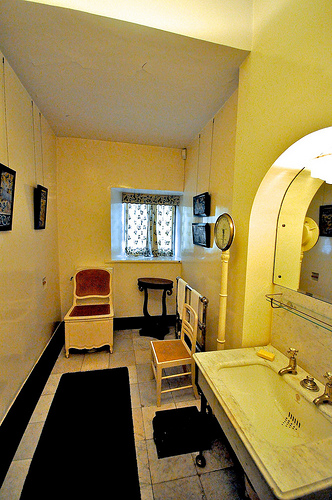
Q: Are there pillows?
A: No, there are no pillows.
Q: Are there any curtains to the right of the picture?
A: Yes, there is a curtain to the right of the picture.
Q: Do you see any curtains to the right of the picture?
A: Yes, there is a curtain to the right of the picture.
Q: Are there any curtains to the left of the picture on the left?
A: No, the curtain is to the right of the picture.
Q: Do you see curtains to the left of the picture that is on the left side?
A: No, the curtain is to the right of the picture.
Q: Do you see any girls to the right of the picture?
A: No, there is a curtain to the right of the picture.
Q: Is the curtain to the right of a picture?
A: Yes, the curtain is to the right of a picture.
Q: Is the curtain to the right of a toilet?
A: No, the curtain is to the right of a picture.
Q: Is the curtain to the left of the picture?
A: No, the curtain is to the right of the picture.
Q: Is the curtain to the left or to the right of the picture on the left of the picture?
A: The curtain is to the right of the picture.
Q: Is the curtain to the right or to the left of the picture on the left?
A: The curtain is to the right of the picture.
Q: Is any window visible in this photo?
A: Yes, there is a window.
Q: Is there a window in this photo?
A: Yes, there is a window.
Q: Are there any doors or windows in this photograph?
A: Yes, there is a window.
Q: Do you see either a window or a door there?
A: Yes, there is a window.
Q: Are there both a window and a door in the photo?
A: No, there is a window but no doors.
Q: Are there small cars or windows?
A: Yes, there is a small window.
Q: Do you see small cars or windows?
A: Yes, there is a small window.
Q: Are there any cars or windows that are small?
A: Yes, the window is small.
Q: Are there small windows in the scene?
A: Yes, there is a small window.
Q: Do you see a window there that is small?
A: Yes, there is a window that is small.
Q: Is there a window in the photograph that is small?
A: Yes, there is a window that is small.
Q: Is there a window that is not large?
A: Yes, there is a small window.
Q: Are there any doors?
A: No, there are no doors.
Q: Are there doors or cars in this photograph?
A: No, there are no doors or cars.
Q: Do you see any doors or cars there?
A: No, there are no doors or cars.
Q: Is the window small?
A: Yes, the window is small.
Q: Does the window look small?
A: Yes, the window is small.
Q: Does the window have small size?
A: Yes, the window is small.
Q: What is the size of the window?
A: The window is small.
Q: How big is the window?
A: The window is small.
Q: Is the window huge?
A: No, the window is small.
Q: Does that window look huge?
A: No, the window is small.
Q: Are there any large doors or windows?
A: No, there is a window but it is small.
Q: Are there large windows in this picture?
A: No, there is a window but it is small.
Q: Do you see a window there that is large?
A: No, there is a window but it is small.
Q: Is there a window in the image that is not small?
A: No, there is a window but it is small.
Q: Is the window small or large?
A: The window is small.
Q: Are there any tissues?
A: No, there are no tissues.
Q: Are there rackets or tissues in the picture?
A: No, there are no tissues or rackets.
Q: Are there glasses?
A: No, there are no glasses.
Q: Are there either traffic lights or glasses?
A: No, there are no glasses or traffic lights.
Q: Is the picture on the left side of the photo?
A: Yes, the picture is on the left of the image.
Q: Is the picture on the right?
A: No, the picture is on the left of the image.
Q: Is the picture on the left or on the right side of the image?
A: The picture is on the left of the image.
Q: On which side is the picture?
A: The picture is on the left of the image.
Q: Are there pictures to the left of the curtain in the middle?
A: Yes, there is a picture to the left of the curtain.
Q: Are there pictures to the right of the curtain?
A: No, the picture is to the left of the curtain.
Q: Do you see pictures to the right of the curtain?
A: No, the picture is to the left of the curtain.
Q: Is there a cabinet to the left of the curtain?
A: No, there is a picture to the left of the curtain.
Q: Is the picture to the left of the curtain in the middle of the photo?
A: Yes, the picture is to the left of the curtain.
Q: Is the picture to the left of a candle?
A: No, the picture is to the left of the curtain.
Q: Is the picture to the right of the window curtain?
A: No, the picture is to the left of the curtain.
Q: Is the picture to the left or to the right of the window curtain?
A: The picture is to the left of the curtain.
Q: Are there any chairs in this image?
A: Yes, there is a chair.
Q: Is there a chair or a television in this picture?
A: Yes, there is a chair.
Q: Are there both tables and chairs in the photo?
A: Yes, there are both a chair and a table.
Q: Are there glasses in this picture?
A: No, there are no glasses.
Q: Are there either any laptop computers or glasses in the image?
A: No, there are no glasses or laptop computers.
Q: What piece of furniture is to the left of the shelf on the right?
A: The piece of furniture is a chair.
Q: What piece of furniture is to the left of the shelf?
A: The piece of furniture is a chair.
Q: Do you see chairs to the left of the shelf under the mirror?
A: Yes, there is a chair to the left of the shelf.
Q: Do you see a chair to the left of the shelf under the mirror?
A: Yes, there is a chair to the left of the shelf.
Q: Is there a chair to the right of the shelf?
A: No, the chair is to the left of the shelf.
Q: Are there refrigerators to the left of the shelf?
A: No, there is a chair to the left of the shelf.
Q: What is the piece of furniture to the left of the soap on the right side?
A: The piece of furniture is a chair.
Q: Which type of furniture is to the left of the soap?
A: The piece of furniture is a chair.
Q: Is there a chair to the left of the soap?
A: Yes, there is a chair to the left of the soap.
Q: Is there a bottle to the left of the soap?
A: No, there is a chair to the left of the soap.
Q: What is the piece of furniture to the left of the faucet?
A: The piece of furniture is a chair.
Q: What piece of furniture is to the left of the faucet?
A: The piece of furniture is a chair.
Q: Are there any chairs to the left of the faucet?
A: Yes, there is a chair to the left of the faucet.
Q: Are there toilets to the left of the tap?
A: No, there is a chair to the left of the tap.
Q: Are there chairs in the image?
A: Yes, there is a chair.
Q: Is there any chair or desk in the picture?
A: Yes, there is a chair.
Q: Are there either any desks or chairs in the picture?
A: Yes, there is a chair.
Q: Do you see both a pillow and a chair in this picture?
A: No, there is a chair but no pillows.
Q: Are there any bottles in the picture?
A: No, there are no bottles.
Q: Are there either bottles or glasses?
A: No, there are no bottles or glasses.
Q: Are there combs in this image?
A: No, there are no combs.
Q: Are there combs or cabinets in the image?
A: No, there are no combs or cabinets.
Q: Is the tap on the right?
A: Yes, the tap is on the right of the image.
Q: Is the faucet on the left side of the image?
A: No, the faucet is on the right of the image.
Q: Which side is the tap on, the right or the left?
A: The tap is on the right of the image.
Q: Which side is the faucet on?
A: The faucet is on the right of the image.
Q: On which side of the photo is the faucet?
A: The faucet is on the right of the image.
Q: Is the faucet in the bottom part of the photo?
A: Yes, the faucet is in the bottom of the image.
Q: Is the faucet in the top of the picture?
A: No, the faucet is in the bottom of the image.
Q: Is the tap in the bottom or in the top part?
A: The tap is in the bottom of the image.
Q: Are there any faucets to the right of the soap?
A: Yes, there is a faucet to the right of the soap.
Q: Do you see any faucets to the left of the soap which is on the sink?
A: No, the faucet is to the right of the soap.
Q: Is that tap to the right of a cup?
A: No, the tap is to the right of the soap.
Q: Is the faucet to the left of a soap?
A: No, the faucet is to the right of a soap.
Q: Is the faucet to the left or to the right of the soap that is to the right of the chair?
A: The faucet is to the right of the soap.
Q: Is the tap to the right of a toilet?
A: No, the tap is to the right of the chair.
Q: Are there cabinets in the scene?
A: No, there are no cabinets.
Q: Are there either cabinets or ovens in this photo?
A: No, there are no cabinets or ovens.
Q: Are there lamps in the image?
A: No, there are no lamps.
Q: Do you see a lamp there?
A: No, there are no lamps.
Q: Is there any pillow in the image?
A: No, there are no pillows.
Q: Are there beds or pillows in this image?
A: No, there are no pillows or beds.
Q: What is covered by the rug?
A: The floor is covered by the rug.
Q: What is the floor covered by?
A: The floor is covered by the rug.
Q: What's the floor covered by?
A: The floor is covered by the rug.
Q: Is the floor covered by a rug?
A: Yes, the floor is covered by a rug.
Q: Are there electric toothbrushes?
A: No, there are no electric toothbrushes.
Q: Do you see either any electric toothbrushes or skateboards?
A: No, there are no electric toothbrushes or skateboards.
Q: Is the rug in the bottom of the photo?
A: Yes, the rug is in the bottom of the image.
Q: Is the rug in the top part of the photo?
A: No, the rug is in the bottom of the image.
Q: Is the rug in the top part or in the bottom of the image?
A: The rug is in the bottom of the image.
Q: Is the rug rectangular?
A: Yes, the rug is rectangular.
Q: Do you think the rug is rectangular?
A: Yes, the rug is rectangular.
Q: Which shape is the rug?
A: The rug is rectangular.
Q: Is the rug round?
A: No, the rug is rectangular.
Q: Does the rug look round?
A: No, the rug is rectangular.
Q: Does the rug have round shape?
A: No, the rug is rectangular.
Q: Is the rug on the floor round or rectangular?
A: The rug is rectangular.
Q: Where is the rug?
A: The rug is on the floor.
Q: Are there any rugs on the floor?
A: Yes, there is a rug on the floor.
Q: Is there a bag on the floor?
A: No, there is a rug on the floor.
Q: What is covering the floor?
A: The rug is covering the floor.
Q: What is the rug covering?
A: The rug is covering the floor.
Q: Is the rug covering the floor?
A: Yes, the rug is covering the floor.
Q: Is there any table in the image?
A: Yes, there is a table.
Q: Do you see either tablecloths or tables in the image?
A: Yes, there is a table.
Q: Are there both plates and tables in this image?
A: No, there is a table but no plates.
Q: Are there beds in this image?
A: No, there are no beds.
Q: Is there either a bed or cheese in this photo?
A: No, there are no beds or cheese.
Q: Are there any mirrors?
A: Yes, there is a mirror.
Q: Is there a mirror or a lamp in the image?
A: Yes, there is a mirror.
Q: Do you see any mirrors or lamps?
A: Yes, there is a mirror.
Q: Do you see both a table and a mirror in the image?
A: Yes, there are both a mirror and a table.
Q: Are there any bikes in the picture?
A: No, there are no bikes.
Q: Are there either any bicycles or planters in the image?
A: No, there are no bicycles or planters.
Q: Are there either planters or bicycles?
A: No, there are no bicycles or planters.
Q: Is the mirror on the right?
A: Yes, the mirror is on the right of the image.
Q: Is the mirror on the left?
A: No, the mirror is on the right of the image.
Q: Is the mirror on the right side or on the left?
A: The mirror is on the right of the image.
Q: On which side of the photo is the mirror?
A: The mirror is on the right of the image.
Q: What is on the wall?
A: The mirror is on the wall.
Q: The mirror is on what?
A: The mirror is on the wall.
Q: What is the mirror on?
A: The mirror is on the wall.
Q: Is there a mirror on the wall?
A: Yes, there is a mirror on the wall.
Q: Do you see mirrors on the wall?
A: Yes, there is a mirror on the wall.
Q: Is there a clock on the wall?
A: No, there is a mirror on the wall.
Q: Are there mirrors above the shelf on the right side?
A: Yes, there is a mirror above the shelf.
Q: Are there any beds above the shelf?
A: No, there is a mirror above the shelf.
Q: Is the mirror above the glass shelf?
A: Yes, the mirror is above the shelf.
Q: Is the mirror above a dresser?
A: No, the mirror is above the shelf.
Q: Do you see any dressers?
A: No, there are no dressers.